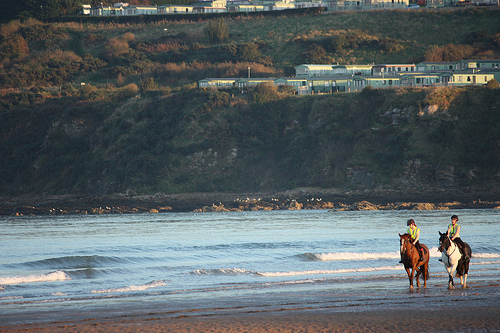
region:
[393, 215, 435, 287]
brown horse with rider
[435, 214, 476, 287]
black and white horse with rider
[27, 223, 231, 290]
blue and white waves on water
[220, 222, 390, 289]
blue and white waves on water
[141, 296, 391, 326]
wet brown sand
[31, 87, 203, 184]
brown grass on hill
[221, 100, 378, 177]
brown grass on hill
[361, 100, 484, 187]
brown grass on hill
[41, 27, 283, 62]
brown grass on hill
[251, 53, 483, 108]
multicolored buildings on hill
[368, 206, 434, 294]
A woman riding a brown horse.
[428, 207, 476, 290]
A woman riding a white horse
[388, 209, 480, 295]
Two women riding horses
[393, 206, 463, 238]
Two women wearing green shirts.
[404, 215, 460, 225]
Two women wearing riding helmets.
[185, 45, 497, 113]
Houses on top of a hill.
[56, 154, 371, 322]
The sound side of the ocean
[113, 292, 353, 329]
Sand on the beach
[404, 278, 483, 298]
Two horses hooves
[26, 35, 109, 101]
Bushes on the side of the hill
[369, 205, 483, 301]
Two people ride horses.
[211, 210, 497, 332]
They ride horses along the shore.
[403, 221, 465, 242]
The riders' tops are green.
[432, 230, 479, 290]
The horse is brown and white.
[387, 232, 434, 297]
The horse is tan.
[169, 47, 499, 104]
Buildings are on the cliff.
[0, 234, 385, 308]
Waves are in the water.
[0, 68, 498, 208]
A cliff is behind the water.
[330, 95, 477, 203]
The cliff is rocky.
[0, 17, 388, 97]
Shrubs and grass grow on the cliff.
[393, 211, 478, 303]
two people riding horses on an empty beach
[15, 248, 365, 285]
waves in the ocean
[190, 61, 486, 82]
several homes facing the ocean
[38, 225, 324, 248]
a serene blue ocean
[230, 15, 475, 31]
a grassy area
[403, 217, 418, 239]
a female rider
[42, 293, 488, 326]
a wet shoreline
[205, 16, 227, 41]
a bush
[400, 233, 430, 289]
a beautiful brown horse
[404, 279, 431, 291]
a horse's hoofs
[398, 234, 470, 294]
these are horse in the beach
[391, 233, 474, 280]
the horse are two in number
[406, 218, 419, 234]
this is a child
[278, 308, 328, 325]
this is sand in the beach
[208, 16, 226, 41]
this is a tree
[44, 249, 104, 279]
these are waves in the sea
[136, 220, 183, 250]
this is a water mass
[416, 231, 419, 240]
the child has light skin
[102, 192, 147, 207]
these are small stones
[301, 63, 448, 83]
these are houses next to the beach